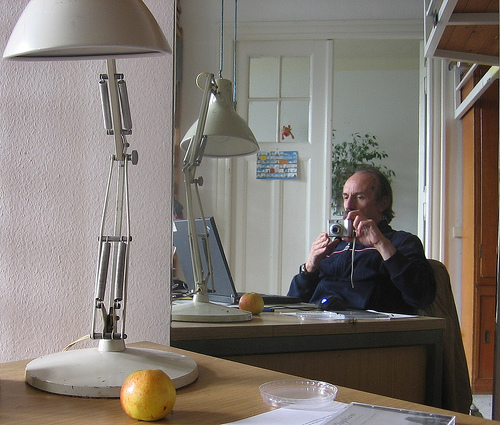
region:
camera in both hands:
[306, 201, 408, 267]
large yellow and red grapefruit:
[110, 360, 170, 424]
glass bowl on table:
[259, 372, 349, 424]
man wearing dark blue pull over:
[298, 164, 443, 311]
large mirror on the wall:
[168, 61, 498, 385]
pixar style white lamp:
[182, 70, 287, 322]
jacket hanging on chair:
[417, 254, 484, 419]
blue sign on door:
[249, 147, 316, 192]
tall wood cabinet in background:
[460, 141, 497, 411]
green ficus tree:
[319, 128, 406, 243]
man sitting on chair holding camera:
[257, 142, 459, 361]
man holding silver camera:
[320, 202, 371, 261]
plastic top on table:
[236, 332, 363, 423]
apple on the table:
[88, 365, 205, 423]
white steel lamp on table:
[0, 0, 205, 410]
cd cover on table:
[318, 387, 464, 424]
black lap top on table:
[172, 200, 313, 337]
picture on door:
[245, 112, 322, 206]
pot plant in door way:
[315, 109, 435, 264]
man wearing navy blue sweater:
[275, 219, 440, 315]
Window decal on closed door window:
[276, 118, 300, 146]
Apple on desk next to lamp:
[121, 363, 186, 421]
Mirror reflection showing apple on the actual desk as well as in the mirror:
[103, 207, 298, 415]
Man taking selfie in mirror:
[306, 163, 403, 292]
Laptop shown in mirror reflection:
[171, 214, 291, 321]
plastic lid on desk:
[249, 363, 342, 415]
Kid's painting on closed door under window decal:
[250, 148, 304, 185]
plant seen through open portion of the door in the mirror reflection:
[331, 113, 401, 168]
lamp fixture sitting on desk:
[8, 0, 168, 184]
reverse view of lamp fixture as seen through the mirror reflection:
[179, 67, 261, 179]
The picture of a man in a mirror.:
[41, 17, 478, 405]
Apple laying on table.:
[106, 357, 202, 423]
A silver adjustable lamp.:
[21, 9, 191, 394]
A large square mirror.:
[166, 13, 489, 334]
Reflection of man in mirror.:
[290, 161, 461, 318]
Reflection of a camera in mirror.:
[300, 210, 375, 245]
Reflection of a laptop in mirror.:
[179, 210, 303, 305]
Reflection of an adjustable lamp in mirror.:
[183, 70, 253, 301]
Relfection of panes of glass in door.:
[245, 47, 317, 147]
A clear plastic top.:
[246, 367, 337, 419]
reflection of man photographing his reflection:
[287, 167, 422, 313]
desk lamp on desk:
[1, 3, 203, 398]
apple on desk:
[114, 368, 186, 424]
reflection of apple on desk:
[237, 292, 265, 318]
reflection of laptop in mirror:
[173, 216, 295, 305]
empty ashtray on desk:
[259, 374, 340, 409]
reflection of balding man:
[290, 167, 432, 312]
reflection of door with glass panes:
[230, 37, 333, 299]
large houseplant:
[330, 126, 398, 216]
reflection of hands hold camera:
[307, 208, 380, 255]